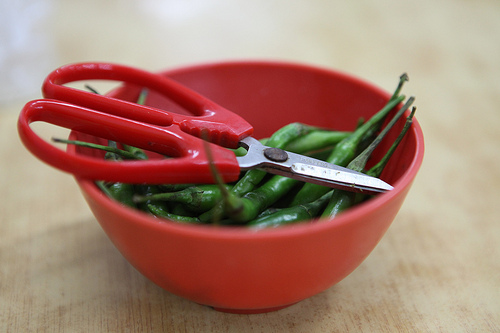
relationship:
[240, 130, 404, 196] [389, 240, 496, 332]
scissor blades on table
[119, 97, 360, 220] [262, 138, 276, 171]
scissor with screw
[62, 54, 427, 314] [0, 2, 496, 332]
bowl on table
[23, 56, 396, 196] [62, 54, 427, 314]
red scissors on bowl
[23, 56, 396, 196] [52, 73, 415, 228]
red scissors on beans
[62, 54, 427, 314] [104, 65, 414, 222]
bowl on green pepper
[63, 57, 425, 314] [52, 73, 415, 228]
bowl with beans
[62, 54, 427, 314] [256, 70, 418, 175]
bowl with beans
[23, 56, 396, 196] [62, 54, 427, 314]
red scissors with bowl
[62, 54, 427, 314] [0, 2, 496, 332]
bowl on a table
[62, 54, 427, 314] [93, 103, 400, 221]
bowl of beans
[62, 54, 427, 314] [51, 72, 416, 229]
bowl filled with green beans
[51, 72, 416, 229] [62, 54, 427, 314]
green beans in bowl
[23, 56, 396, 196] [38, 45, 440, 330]
red scissors in bowl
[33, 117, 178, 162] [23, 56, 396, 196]
hole for red scissors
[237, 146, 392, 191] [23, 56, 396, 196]
blades are on red scissors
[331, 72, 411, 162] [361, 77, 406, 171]
green bean has edge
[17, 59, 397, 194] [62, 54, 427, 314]
kitchen shears are inside bowl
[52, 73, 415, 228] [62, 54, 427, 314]
beans are inside bowl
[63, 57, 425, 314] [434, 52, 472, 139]
bowl on woodentable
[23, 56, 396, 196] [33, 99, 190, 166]
red scissors has handles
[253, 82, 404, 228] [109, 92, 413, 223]
beans has stems